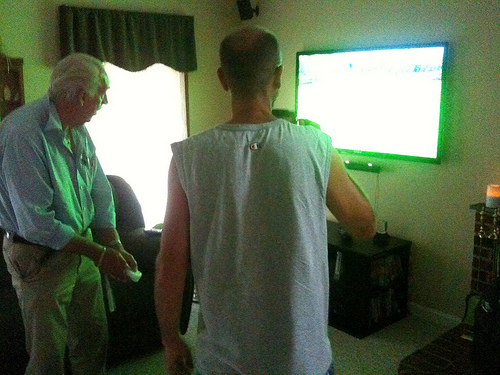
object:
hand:
[93, 243, 132, 285]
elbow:
[351, 213, 377, 242]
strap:
[101, 270, 119, 313]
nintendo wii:
[124, 266, 144, 284]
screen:
[294, 42, 450, 166]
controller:
[122, 258, 142, 284]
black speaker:
[236, 0, 260, 21]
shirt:
[168, 117, 332, 375]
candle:
[484, 185, 500, 210]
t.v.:
[293, 38, 449, 165]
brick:
[397, 323, 500, 375]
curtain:
[56, 3, 198, 75]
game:
[128, 268, 144, 285]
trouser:
[0, 232, 112, 374]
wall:
[237, 0, 499, 313]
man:
[0, 52, 143, 374]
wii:
[125, 267, 143, 282]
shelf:
[0, 53, 29, 121]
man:
[153, 23, 376, 375]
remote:
[124, 267, 143, 283]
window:
[74, 62, 189, 234]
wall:
[0, 0, 65, 111]